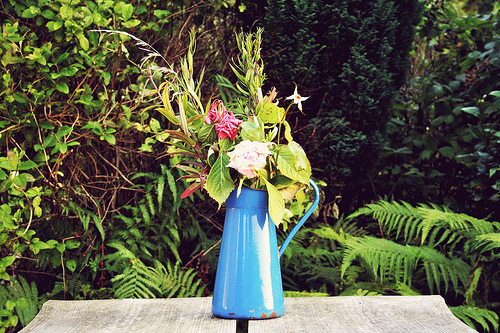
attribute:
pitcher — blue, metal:
[195, 197, 330, 327]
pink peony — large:
[203, 130, 300, 190]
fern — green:
[112, 258, 209, 299]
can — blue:
[212, 179, 320, 319]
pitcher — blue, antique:
[208, 172, 328, 314]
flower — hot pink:
[207, 99, 236, 137]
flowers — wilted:
[205, 90, 270, 177]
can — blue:
[203, 163, 320, 315]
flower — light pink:
[224, 136, 274, 183]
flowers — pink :
[232, 137, 274, 182]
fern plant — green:
[313, 197, 498, 331]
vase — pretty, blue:
[117, 32, 355, 332]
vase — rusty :
[200, 164, 360, 324]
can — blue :
[144, 136, 373, 324]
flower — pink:
[200, 99, 247, 145]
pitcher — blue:
[211, 181, 320, 317]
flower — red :
[207, 101, 242, 140]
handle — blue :
[281, 171, 321, 255]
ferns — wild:
[348, 193, 496, 286]